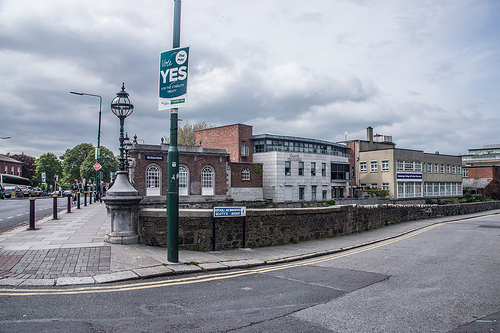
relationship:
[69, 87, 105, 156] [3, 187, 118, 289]
lamp in sidewalk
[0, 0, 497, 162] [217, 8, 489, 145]
cloud are part of sky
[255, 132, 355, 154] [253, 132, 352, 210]
top roof portion of building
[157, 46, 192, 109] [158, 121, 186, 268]
advertisement on metal post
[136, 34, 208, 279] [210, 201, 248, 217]
post next to board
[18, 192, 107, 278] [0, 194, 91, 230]
side walk beside road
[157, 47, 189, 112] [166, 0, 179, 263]
sign on post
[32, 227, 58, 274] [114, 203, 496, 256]
sidewalk under wall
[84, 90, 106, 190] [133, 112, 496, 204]
lamp post near buildings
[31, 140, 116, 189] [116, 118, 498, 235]
trees behind buildings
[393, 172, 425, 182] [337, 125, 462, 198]
sign on building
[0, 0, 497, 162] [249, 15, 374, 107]
cloud are part of sky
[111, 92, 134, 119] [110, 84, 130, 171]
globe atop post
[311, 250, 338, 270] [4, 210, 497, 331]
line painted on street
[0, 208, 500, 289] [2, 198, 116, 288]
sidewalk intersects sidewalk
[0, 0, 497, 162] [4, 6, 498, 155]
cloud in sky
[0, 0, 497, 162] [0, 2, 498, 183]
cloud in sky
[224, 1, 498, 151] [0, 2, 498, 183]
cloud in sky